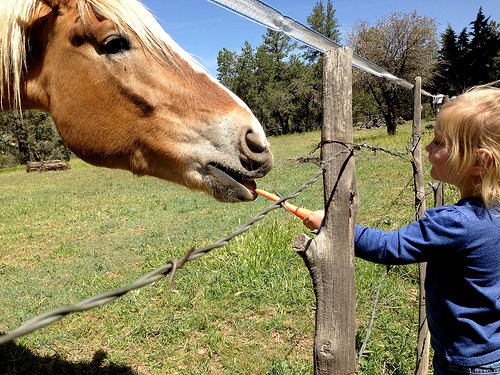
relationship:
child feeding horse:
[301, 79, 499, 374] [2, 0, 274, 220]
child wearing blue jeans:
[301, 79, 499, 374] [427, 361, 499, 373]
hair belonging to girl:
[430, 84, 500, 210] [444, 96, 499, 341]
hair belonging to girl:
[430, 84, 500, 210] [400, 107, 490, 252]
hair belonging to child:
[435, 85, 499, 205] [301, 79, 499, 374]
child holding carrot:
[301, 79, 499, 374] [249, 185, 311, 219]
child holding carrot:
[301, 79, 499, 374] [250, 182, 315, 219]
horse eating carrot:
[2, 0, 274, 220] [250, 182, 315, 219]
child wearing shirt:
[301, 79, 499, 374] [348, 198, 498, 362]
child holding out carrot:
[322, 81, 499, 373] [253, 188, 312, 222]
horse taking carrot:
[2, 0, 274, 220] [253, 182, 306, 224]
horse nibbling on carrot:
[2, 0, 274, 220] [226, 170, 378, 268]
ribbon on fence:
[217, 0, 446, 102] [0, 3, 457, 372]